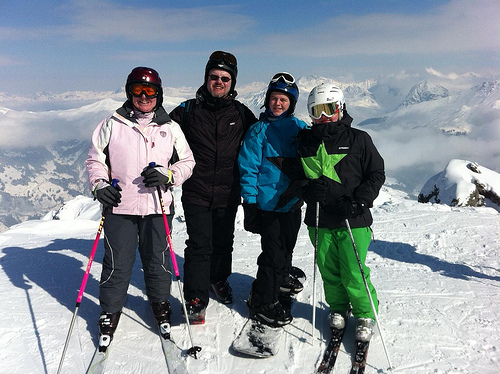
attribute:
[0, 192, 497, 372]
snow — white 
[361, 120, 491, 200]
clouds — group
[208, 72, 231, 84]
sunglasses — man's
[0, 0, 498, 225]
landscape — large mountainous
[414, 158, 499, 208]
rock — Small 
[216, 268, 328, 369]
snowboard — girl's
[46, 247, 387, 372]
skier — man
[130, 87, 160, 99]
goggles — orange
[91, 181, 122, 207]
right glove — woman's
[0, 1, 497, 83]
clouds — white 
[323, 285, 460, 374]
ski — Pink 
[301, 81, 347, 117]
helment — White 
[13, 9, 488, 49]
clouds — white 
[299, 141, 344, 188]
star — green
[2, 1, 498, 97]
sky — blue 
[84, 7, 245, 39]
clouds — white 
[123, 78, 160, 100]
goggles — woman's, ski